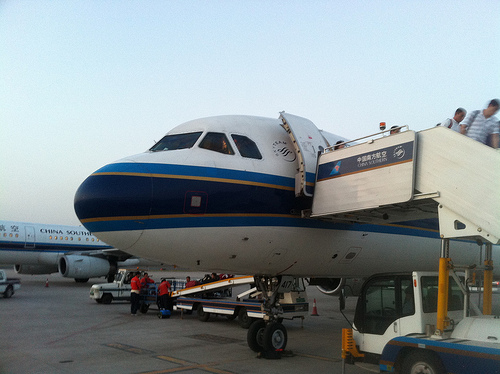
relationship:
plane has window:
[49, 69, 461, 323] [209, 139, 275, 162]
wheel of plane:
[231, 313, 305, 363] [49, 69, 461, 323]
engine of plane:
[63, 246, 121, 285] [49, 69, 461, 323]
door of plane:
[282, 105, 344, 205] [49, 69, 461, 323]